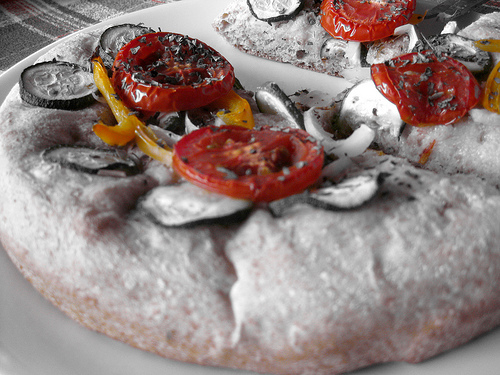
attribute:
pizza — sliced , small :
[0, 0, 498, 374]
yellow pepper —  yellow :
[88, 61, 255, 167]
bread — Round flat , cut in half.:
[91, 63, 378, 283]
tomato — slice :
[365, 46, 483, 130]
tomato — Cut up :
[111, 0, 481, 200]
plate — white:
[35, 8, 472, 373]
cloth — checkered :
[8, 12, 58, 41]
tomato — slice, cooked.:
[109, 25, 237, 115]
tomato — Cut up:
[113, 30, 234, 108]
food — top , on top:
[1, 22, 498, 373]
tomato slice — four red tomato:
[370, 45, 479, 127]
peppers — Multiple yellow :
[86, 59, 253, 166]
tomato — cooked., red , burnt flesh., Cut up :
[108, 25, 239, 123]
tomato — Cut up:
[167, 120, 330, 206]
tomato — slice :
[118, 32, 225, 114]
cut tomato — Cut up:
[116, 28, 335, 206]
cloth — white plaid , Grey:
[0, 1, 136, 73]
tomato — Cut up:
[365, 45, 476, 127]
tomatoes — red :
[118, 48, 263, 184]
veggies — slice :
[38, 16, 498, 200]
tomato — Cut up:
[174, 112, 319, 204]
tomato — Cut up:
[177, 110, 322, 209]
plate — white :
[21, 6, 498, 342]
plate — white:
[12, 301, 65, 366]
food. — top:
[58, 34, 350, 221]